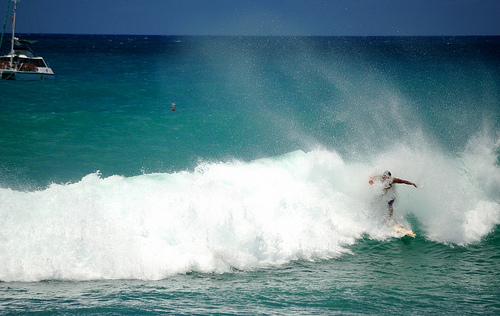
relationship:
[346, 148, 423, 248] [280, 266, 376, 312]
surfer in water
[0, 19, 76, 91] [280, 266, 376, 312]
boat in water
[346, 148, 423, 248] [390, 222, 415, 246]
surfer on board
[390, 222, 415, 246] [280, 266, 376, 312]
board in water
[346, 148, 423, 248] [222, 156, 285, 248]
surfer riding wave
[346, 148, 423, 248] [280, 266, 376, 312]
surfer riding water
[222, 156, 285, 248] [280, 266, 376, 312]
wave in water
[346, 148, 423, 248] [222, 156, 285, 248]
surfer in wave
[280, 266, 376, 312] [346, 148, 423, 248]
water surrounding surfer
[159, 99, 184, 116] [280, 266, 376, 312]
buoy in water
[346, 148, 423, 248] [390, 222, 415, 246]
surfer riding board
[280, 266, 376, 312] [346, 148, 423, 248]
water around surfer